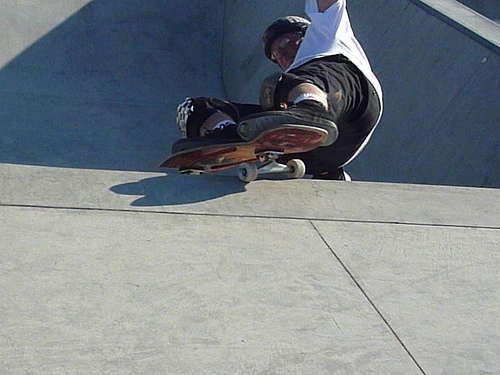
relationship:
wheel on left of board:
[235, 160, 256, 181] [156, 123, 326, 183]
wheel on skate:
[291, 159, 307, 179] [158, 121, 329, 182]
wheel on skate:
[237, 162, 257, 183] [158, 121, 329, 182]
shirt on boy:
[285, 0, 384, 70] [161, 2, 385, 182]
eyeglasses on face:
[271, 34, 302, 60] [267, 29, 305, 71]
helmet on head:
[259, 15, 310, 51] [259, 14, 313, 71]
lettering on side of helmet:
[287, 14, 307, 22] [261, 15, 311, 64]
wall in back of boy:
[2, 1, 498, 185] [170, 0, 384, 173]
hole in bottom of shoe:
[239, 120, 249, 133] [234, 102, 339, 144]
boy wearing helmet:
[170, 0, 384, 173] [261, 15, 311, 64]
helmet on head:
[261, 15, 311, 64] [259, 14, 313, 71]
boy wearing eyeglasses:
[170, 0, 384, 173] [271, 34, 302, 60]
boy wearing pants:
[170, 0, 384, 173] [175, 53, 381, 174]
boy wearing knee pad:
[170, 0, 384, 173] [176, 96, 211, 136]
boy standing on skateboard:
[170, 0, 384, 173] [154, 122, 329, 178]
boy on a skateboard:
[170, 0, 384, 173] [154, 122, 329, 178]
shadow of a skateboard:
[109, 170, 246, 206] [154, 122, 329, 178]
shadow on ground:
[109, 170, 246, 206] [0, 164, 497, 372]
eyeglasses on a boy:
[269, 35, 300, 60] [170, 0, 384, 173]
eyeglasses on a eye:
[269, 35, 300, 60] [269, 48, 278, 58]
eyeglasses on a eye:
[269, 35, 300, 60] [278, 37, 292, 47]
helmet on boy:
[261, 15, 311, 64] [170, 0, 384, 173]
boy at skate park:
[170, 0, 384, 173] [4, 4, 498, 373]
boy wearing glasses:
[170, 0, 384, 173] [262, 26, 307, 66]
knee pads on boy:
[168, 77, 295, 122] [170, 0, 384, 173]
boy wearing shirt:
[170, 0, 384, 173] [281, 6, 393, 106]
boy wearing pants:
[170, 0, 384, 173] [320, 66, 346, 112]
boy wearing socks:
[170, 0, 384, 173] [288, 87, 324, 109]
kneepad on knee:
[160, 101, 230, 132] [184, 92, 221, 133]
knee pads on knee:
[258, 70, 284, 110] [256, 77, 316, 101]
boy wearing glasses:
[170, 0, 384, 173] [252, 34, 316, 64]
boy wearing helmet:
[170, 0, 384, 173] [249, 36, 279, 43]